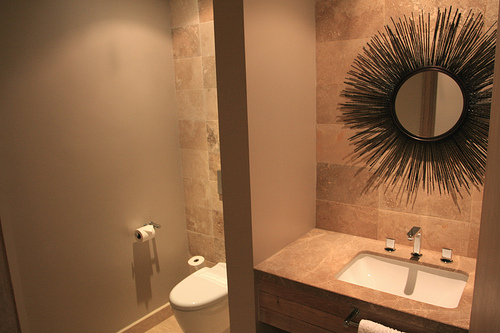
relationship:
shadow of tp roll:
[133, 242, 154, 308] [133, 225, 156, 243]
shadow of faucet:
[402, 266, 420, 294] [408, 225, 424, 259]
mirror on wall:
[395, 69, 465, 140] [305, 0, 497, 260]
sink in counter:
[335, 250, 468, 309] [252, 227, 478, 330]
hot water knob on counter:
[383, 238, 397, 253] [252, 227, 478, 330]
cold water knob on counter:
[441, 246, 454, 263] [252, 227, 478, 330]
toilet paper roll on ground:
[188, 256, 206, 272] [131, 311, 186, 332]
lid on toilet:
[169, 266, 230, 309] [167, 261, 232, 332]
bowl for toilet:
[172, 309, 231, 331] [167, 261, 232, 332]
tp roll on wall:
[133, 225, 156, 243] [0, 0, 192, 332]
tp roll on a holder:
[133, 225, 156, 243] [150, 222, 160, 230]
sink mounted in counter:
[335, 250, 468, 309] [252, 227, 478, 330]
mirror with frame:
[395, 69, 465, 140] [339, 8, 496, 213]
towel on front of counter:
[359, 319, 409, 332] [252, 227, 478, 330]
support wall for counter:
[213, 1, 314, 331] [252, 227, 478, 330]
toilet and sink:
[167, 261, 232, 332] [335, 250, 468, 309]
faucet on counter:
[408, 225, 424, 259] [252, 227, 478, 330]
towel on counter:
[359, 319, 409, 332] [252, 227, 478, 330]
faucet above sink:
[408, 225, 424, 259] [335, 250, 468, 309]